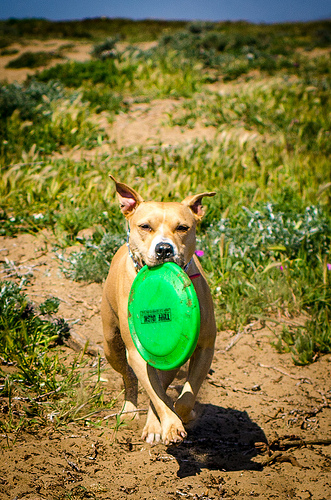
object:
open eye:
[138, 220, 154, 233]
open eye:
[173, 221, 190, 233]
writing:
[139, 307, 170, 323]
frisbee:
[126, 260, 201, 373]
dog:
[101, 175, 217, 453]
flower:
[192, 246, 207, 258]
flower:
[276, 258, 284, 279]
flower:
[322, 258, 330, 277]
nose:
[154, 241, 173, 262]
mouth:
[141, 254, 177, 277]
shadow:
[165, 401, 268, 479]